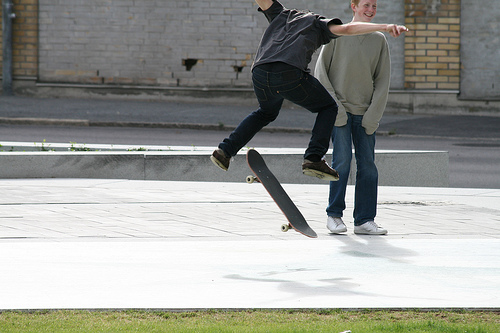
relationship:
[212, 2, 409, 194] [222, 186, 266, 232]
skateboarder in air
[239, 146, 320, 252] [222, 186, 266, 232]
skateboard in air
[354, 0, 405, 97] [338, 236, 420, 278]
other boy has shadow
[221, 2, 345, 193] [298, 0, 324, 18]
skateboarder appears headless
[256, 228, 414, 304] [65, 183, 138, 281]
shadows on ground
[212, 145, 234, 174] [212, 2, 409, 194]
shoe of skateboarder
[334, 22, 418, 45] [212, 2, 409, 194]
arm of skateboarder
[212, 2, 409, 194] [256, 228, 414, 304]
skateboarder casts shadows